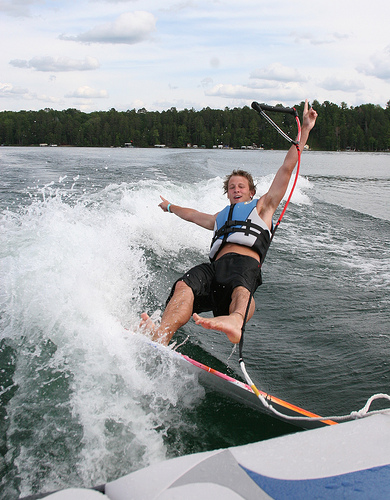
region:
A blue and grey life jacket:
[206, 199, 271, 258]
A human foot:
[191, 309, 246, 341]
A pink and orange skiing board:
[124, 324, 334, 430]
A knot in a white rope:
[347, 406, 363, 418]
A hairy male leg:
[158, 279, 197, 322]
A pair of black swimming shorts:
[163, 253, 263, 313]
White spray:
[18, 250, 167, 458]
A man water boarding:
[142, 93, 340, 423]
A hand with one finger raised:
[303, 98, 316, 129]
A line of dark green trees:
[0, 101, 388, 151]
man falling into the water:
[67, 87, 357, 427]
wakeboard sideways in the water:
[111, 323, 346, 437]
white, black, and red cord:
[235, 142, 377, 420]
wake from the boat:
[5, 169, 314, 498]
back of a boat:
[22, 409, 385, 499]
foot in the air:
[191, 300, 251, 346]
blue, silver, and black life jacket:
[197, 196, 276, 257]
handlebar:
[242, 93, 312, 148]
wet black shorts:
[148, 244, 267, 318]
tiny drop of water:
[162, 282, 175, 294]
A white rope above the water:
[234, 363, 271, 407]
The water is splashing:
[40, 337, 136, 446]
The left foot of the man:
[192, 302, 242, 335]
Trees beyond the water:
[116, 112, 238, 138]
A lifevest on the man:
[213, 209, 255, 244]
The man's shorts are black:
[189, 257, 240, 299]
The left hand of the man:
[301, 105, 318, 135]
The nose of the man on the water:
[232, 186, 241, 194]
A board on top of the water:
[154, 342, 288, 414]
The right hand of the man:
[152, 197, 173, 211]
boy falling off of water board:
[117, 98, 356, 427]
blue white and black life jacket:
[208, 199, 274, 255]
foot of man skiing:
[188, 307, 245, 346]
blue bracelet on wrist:
[165, 201, 169, 211]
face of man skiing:
[219, 166, 250, 201]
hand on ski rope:
[250, 96, 303, 146]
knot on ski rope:
[351, 407, 361, 418]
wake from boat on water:
[3, 175, 140, 464]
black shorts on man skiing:
[170, 248, 258, 299]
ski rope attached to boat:
[233, 100, 382, 429]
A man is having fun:
[152, 156, 271, 369]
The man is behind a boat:
[147, 185, 292, 368]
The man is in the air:
[154, 154, 298, 348]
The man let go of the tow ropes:
[248, 101, 301, 366]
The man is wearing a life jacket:
[196, 183, 272, 269]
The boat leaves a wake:
[45, 191, 151, 445]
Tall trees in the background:
[15, 113, 265, 145]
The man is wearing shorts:
[180, 253, 275, 304]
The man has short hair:
[221, 161, 257, 196]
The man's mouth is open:
[229, 191, 251, 209]